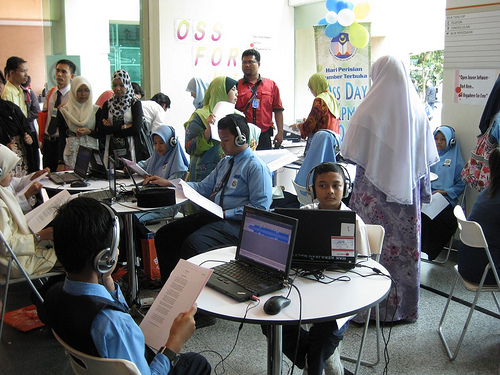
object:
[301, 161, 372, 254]
child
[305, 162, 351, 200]
headphones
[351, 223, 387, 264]
chair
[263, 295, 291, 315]
mouse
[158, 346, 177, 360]
watch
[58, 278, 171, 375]
shirt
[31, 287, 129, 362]
vest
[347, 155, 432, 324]
dress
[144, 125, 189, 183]
headscarf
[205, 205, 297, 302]
laptop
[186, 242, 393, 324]
table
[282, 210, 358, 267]
laptop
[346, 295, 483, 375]
floor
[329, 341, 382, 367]
base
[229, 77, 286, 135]
shirt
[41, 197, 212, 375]
boy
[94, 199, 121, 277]
headphones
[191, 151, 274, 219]
shirt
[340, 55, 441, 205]
headscarf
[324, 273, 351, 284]
cables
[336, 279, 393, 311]
edge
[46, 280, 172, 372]
clothes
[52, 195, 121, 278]
head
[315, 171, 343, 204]
face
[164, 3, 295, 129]
wall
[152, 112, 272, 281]
people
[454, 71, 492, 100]
paper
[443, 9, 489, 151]
wall